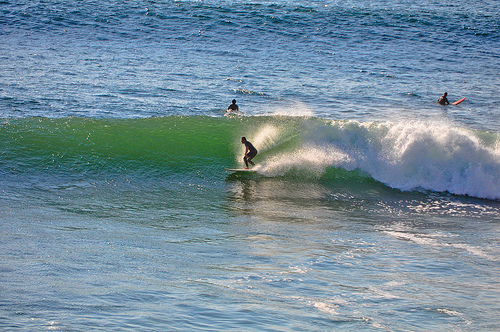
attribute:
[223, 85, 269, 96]
wave — small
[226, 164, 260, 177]
surfboard — red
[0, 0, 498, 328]
ocean — calm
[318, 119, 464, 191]
wave crest — white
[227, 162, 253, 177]
surfboard — white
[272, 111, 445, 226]
foam — white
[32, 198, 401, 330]
ripples — in ocean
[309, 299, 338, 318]
foam — white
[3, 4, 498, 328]
water — calm, green, ocean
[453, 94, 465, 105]
board — red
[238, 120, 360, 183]
spray — white